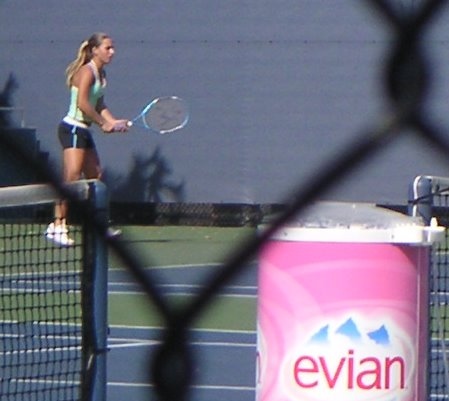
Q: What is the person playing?
A: Tennis.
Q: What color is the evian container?
A: Pink.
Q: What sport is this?
A: Tennis.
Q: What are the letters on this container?
A: Evian.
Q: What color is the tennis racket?
A: The racket is blue.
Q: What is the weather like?
A: The sun is shining.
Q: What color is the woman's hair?
A: Her hair is blonde.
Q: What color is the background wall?
A: The background is dark green.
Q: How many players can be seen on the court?
A: Only one player can be seen on the court.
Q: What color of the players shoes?
A: Woman's shoes are white.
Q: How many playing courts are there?
A: There are two playing courts.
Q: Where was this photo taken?
A: At an outside tennis court.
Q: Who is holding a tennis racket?
A: A woman with long hair.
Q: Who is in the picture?
A: A woman wearing a blue top.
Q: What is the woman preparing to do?
A: Hit a tennis ball.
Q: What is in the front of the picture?
A: Pink Evian trash can.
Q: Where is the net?
A: At a tennis court.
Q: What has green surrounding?
A: Blue tennis court.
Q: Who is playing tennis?
A: Blonde tennis player with a green shirt.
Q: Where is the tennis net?
A: On the court.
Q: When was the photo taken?
A: At day time.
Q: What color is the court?
A: Green and blue.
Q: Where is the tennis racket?
A: Woman's hands.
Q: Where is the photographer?
A: Behind chain link fence.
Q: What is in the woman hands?
A: Tennis racket.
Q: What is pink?
A: Evian cooler.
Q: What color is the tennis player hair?
A: Blonde.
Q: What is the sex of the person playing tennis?
A: It's a woman.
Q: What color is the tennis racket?
A: Blue.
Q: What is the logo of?
A: Evian.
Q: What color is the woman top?
A: Light green.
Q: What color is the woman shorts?
A: Black.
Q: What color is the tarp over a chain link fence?
A: Blue.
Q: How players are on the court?
A: One.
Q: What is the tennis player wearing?
A: A tank top and shorts.